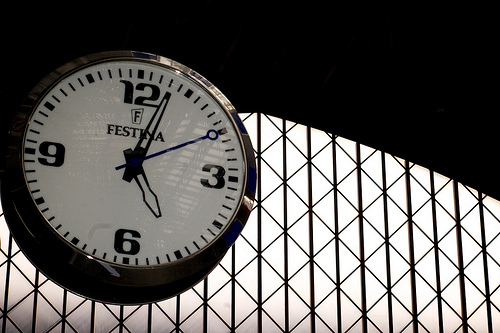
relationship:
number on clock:
[117, 78, 162, 108] [35, 73, 295, 266]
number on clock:
[94, 229, 153, 269] [42, 70, 286, 286]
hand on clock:
[120, 91, 175, 183] [36, 81, 273, 288]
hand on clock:
[112, 130, 217, 172] [43, 80, 237, 264]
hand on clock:
[112, 130, 217, 172] [45, 62, 299, 311]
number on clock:
[24, 125, 105, 198] [75, 71, 335, 312]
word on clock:
[96, 117, 182, 152] [48, 60, 288, 267]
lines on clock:
[25, 182, 77, 231] [29, 77, 231, 235]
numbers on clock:
[181, 153, 237, 185] [15, 63, 259, 292]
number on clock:
[117, 78, 162, 108] [25, 60, 275, 289]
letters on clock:
[113, 101, 194, 154] [42, 65, 275, 270]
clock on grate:
[21, 58, 309, 322] [224, 140, 423, 311]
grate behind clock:
[240, 142, 466, 329] [36, 58, 267, 265]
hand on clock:
[112, 130, 217, 172] [35, 66, 284, 259]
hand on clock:
[120, 91, 175, 183] [15, 66, 303, 294]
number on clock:
[117, 78, 162, 108] [39, 60, 238, 260]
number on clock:
[103, 63, 181, 116] [51, 33, 350, 305]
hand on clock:
[120, 91, 175, 183] [24, 52, 251, 284]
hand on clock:
[122, 144, 167, 221] [1, 46, 260, 316]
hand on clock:
[117, 130, 217, 173] [24, 52, 251, 284]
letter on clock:
[125, 102, 151, 132] [24, 52, 251, 284]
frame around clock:
[1, 51, 265, 303] [20, 61, 244, 270]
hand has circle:
[120, 91, 175, 183] [204, 125, 219, 141]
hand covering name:
[125, 87, 176, 184] [102, 117, 174, 147]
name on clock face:
[97, 111, 167, 141] [16, 58, 237, 278]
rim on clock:
[1, 44, 255, 309] [20, 61, 244, 270]